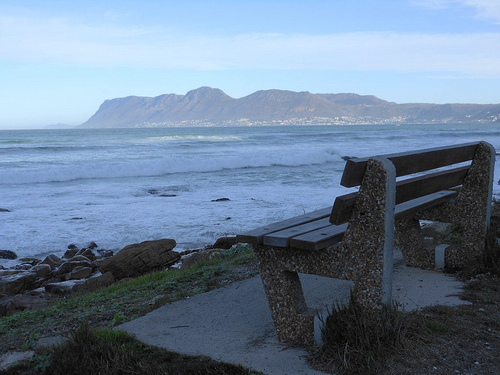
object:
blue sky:
[0, 0, 500, 131]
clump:
[0, 238, 181, 318]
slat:
[350, 159, 397, 217]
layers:
[136, 156, 266, 206]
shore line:
[0, 119, 500, 132]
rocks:
[0, 239, 182, 317]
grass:
[0, 243, 271, 351]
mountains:
[43, 86, 500, 129]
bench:
[235, 140, 495, 347]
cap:
[148, 135, 246, 140]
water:
[0, 122, 500, 262]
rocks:
[259, 264, 315, 349]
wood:
[236, 222, 318, 251]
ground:
[0, 243, 500, 374]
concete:
[110, 219, 475, 375]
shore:
[0, 237, 337, 331]